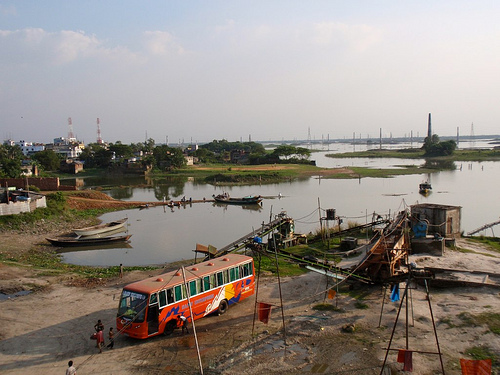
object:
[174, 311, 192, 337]
person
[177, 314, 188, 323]
shirt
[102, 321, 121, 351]
person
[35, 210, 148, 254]
boat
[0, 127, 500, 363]
shore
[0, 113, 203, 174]
factory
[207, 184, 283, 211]
boat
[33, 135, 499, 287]
water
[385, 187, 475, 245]
shack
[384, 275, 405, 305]
flag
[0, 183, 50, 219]
fence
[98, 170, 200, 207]
reflection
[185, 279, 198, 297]
window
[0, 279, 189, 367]
shadow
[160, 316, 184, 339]
tire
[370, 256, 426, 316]
wire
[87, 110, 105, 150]
tower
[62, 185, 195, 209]
ramp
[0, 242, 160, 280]
grass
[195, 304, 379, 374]
mud puddle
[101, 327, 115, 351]
skirt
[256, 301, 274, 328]
cloth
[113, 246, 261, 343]
bus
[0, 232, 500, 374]
mud